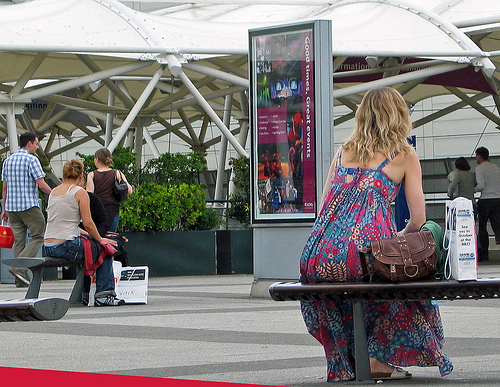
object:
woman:
[298, 84, 454, 379]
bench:
[271, 282, 499, 377]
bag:
[445, 196, 476, 282]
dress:
[296, 146, 453, 382]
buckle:
[404, 264, 419, 278]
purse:
[362, 231, 439, 281]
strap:
[78, 233, 118, 276]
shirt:
[3, 150, 43, 211]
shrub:
[119, 181, 214, 231]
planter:
[125, 230, 217, 276]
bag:
[0, 226, 13, 249]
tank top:
[93, 168, 119, 218]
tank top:
[42, 186, 79, 239]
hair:
[342, 86, 413, 165]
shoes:
[82, 294, 127, 307]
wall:
[417, 125, 500, 148]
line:
[2, 366, 274, 385]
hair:
[95, 148, 113, 164]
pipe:
[279, 6, 489, 64]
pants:
[7, 208, 47, 284]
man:
[0, 132, 52, 290]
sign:
[249, 30, 319, 215]